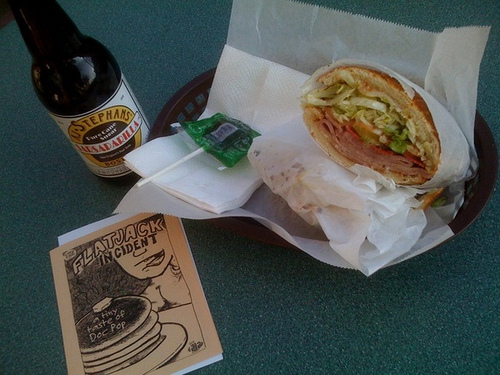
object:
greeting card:
[49, 213, 223, 373]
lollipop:
[135, 111, 262, 190]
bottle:
[10, 1, 152, 186]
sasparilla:
[10, 0, 150, 185]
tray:
[148, 69, 498, 248]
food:
[299, 63, 442, 181]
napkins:
[124, 122, 273, 214]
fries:
[256, 135, 359, 220]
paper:
[249, 134, 426, 252]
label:
[49, 71, 149, 181]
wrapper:
[173, 114, 259, 171]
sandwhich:
[302, 61, 441, 186]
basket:
[142, 64, 499, 249]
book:
[48, 212, 238, 373]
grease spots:
[269, 159, 326, 209]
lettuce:
[316, 80, 417, 152]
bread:
[301, 66, 441, 185]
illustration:
[62, 216, 207, 374]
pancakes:
[77, 293, 167, 373]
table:
[2, 4, 499, 374]